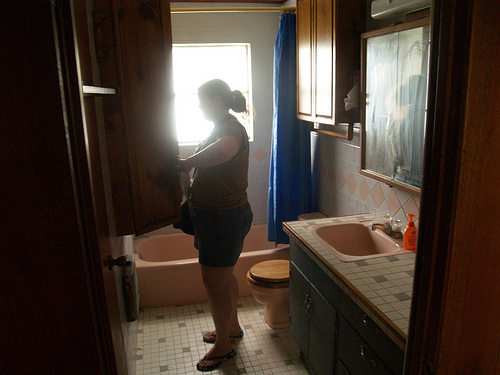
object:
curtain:
[267, 12, 313, 248]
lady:
[176, 78, 253, 371]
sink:
[301, 217, 417, 262]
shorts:
[189, 200, 254, 267]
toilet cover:
[248, 259, 289, 284]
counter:
[340, 252, 423, 340]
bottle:
[403, 212, 419, 250]